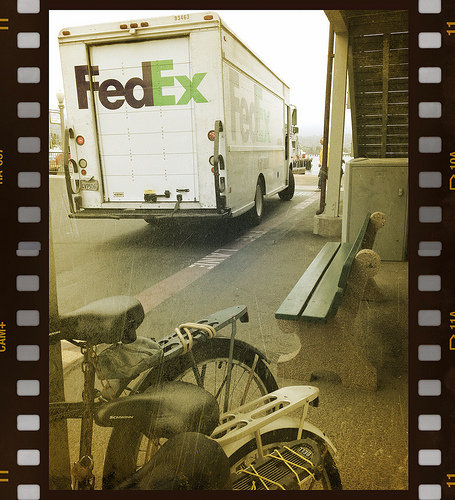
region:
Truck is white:
[53, 11, 318, 225]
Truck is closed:
[52, 13, 304, 240]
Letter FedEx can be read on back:
[66, 46, 212, 126]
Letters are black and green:
[61, 46, 214, 122]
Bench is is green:
[266, 200, 396, 396]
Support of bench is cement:
[276, 208, 394, 403]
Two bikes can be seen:
[59, 274, 347, 498]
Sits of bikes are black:
[68, 284, 222, 486]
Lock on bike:
[68, 442, 107, 487]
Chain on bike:
[70, 347, 111, 458]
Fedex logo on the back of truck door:
[74, 56, 209, 110]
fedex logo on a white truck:
[68, 51, 208, 108]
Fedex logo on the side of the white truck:
[225, 71, 281, 144]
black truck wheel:
[249, 175, 268, 224]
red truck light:
[73, 134, 85, 146]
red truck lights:
[75, 129, 92, 169]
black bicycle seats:
[45, 287, 146, 344]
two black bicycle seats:
[95, 378, 227, 496]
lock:
[69, 454, 98, 481]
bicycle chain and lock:
[72, 344, 99, 494]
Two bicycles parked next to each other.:
[9, 273, 365, 489]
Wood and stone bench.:
[259, 191, 394, 398]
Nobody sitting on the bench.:
[252, 207, 401, 402]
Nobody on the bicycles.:
[11, 274, 368, 489]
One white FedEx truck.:
[52, 11, 317, 219]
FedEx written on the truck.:
[56, 39, 218, 115]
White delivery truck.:
[51, 9, 308, 221]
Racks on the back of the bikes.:
[146, 279, 318, 442]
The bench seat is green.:
[263, 206, 374, 339]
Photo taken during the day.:
[44, 18, 400, 384]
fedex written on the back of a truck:
[73, 52, 212, 119]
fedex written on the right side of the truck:
[224, 66, 284, 155]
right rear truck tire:
[237, 167, 274, 227]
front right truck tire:
[279, 162, 303, 209]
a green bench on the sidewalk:
[258, 192, 404, 349]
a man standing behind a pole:
[306, 129, 335, 209]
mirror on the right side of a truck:
[285, 94, 309, 141]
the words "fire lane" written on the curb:
[180, 221, 275, 286]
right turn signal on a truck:
[198, 122, 223, 153]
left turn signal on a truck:
[68, 124, 84, 159]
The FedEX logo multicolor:
[69, 65, 213, 116]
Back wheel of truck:
[240, 173, 278, 228]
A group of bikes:
[81, 281, 315, 494]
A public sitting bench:
[279, 208, 382, 392]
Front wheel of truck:
[277, 164, 301, 204]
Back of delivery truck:
[56, 30, 213, 201]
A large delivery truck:
[59, 12, 311, 247]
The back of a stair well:
[333, 36, 405, 165]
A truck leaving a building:
[73, 48, 373, 416]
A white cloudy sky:
[264, 17, 315, 60]